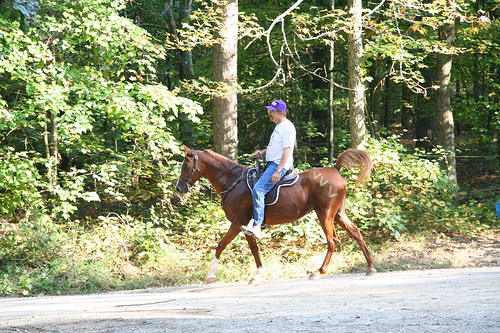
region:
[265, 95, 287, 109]
a blue baseball cap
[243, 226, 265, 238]
a man's shoe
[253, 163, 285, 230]
the leg of a man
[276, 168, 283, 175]
a man's wristwatch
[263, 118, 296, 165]
a man's short sleeve shirt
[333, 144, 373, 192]
a brown horse tail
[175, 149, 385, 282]
a brown horse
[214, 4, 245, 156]
a tall gray branch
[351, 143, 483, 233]
green tree leaves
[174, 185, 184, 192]
the nose of a horse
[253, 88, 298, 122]
Purple hat on man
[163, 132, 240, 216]
Brown horse head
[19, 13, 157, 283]
Thickly settled forrest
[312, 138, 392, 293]
Horse tail on horse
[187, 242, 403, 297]
Horse hooves on gravel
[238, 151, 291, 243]
Mens blue jeans on a man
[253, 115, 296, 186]
White T shirt large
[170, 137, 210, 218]
Black horse harness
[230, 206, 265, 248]
Foot in sturrips of horse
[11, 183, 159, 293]
Big green bushes in forrest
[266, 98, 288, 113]
purple hat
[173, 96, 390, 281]
a man on a horse in a purple hat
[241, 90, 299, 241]
a man in a purple hat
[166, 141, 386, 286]
a horse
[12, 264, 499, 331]
a gravel road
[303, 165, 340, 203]
pattern on the horse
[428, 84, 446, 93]
a leaf on a branch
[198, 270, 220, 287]
the horse's left front hoove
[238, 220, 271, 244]
The man's left foot in a stirrup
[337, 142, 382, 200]
the tail of a horse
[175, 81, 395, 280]
a man riding a horse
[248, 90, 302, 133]
a man wearing a purple hat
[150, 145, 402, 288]
a brown horse with two white feet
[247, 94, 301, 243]
a man wearing blue jeans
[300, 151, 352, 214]
a horse with three letters on it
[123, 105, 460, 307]
a horse walking on a road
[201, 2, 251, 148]
a large tree trunk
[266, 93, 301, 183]
a man wearing a white shirt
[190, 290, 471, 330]
a gravel road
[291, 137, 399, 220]
a horse with its tail raised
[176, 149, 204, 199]
the head of the horse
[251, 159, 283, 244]
a man in a blue jeans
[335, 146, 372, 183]
the erected horsetail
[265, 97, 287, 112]
a purple cap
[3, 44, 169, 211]
a very dense forest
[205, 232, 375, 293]
the four legs of the horse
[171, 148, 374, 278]
a brown horse running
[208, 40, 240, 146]
the thick stem of a tree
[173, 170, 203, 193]
the brake to control the horse